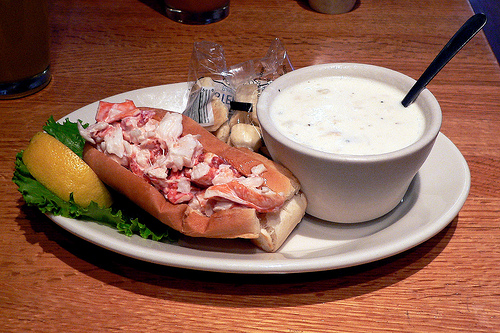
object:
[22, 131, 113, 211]
lemon wedge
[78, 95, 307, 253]
lobster sandwich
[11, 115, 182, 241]
lettuce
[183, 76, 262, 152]
crackers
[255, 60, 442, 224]
bowl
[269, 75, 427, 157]
soup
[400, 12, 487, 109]
spoon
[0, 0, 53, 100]
glass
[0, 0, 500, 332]
table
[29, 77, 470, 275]
plate